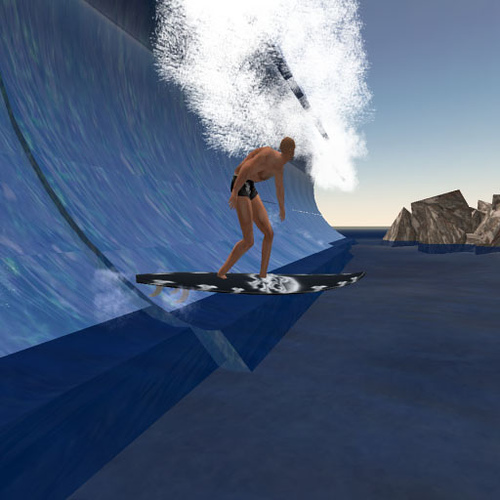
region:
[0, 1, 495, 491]
Virtual picture of a surfboarding man.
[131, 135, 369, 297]
The man is standing on his surfboard.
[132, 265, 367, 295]
The surfboard is black and white.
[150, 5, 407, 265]
The man is under a high tide.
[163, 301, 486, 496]
The water is blue.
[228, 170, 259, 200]
Man is wearing black with white stripe swimsuit.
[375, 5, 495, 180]
The sky is blue and clear.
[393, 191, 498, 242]
Background on the right is rocky.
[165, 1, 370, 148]
The wave is about to splash on the surfboarder.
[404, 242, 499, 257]
The rocks reflect on the water.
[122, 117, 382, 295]
Avatar surfing on the water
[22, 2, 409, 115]
virtual wave of water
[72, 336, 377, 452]
dark blue virtual water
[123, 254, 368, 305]
black and white surf board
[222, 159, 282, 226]
men's black swimming shorts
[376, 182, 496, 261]
virtual rocks on the water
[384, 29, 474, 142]
clear blue virtual sky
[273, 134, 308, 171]
avatar head with blonde hair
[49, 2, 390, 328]
large wave over man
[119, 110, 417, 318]
man surfing on virtual water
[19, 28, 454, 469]
This is an animation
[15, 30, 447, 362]
This is a surfer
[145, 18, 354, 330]
The man is surfing a wave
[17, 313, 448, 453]
This water is very blue and transparent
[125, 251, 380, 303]
This surfboard is black and white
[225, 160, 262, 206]
The man is wearing black shorts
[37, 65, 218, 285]
This is a wave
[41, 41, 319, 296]
The wave is bigger than the man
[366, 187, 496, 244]
These are rocks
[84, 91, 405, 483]
This takes place by the ocean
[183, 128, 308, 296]
Man in the foreground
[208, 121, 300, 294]
Man is surf boarding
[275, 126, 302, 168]
A side view of a man's head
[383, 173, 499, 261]
Large rocks in the background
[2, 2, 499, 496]
Photo is in 3D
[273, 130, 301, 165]
Man in the foreground is bald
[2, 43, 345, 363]
A water wave is behind the man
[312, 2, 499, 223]
The sky is clear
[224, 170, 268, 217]
Man is wearing swim trunks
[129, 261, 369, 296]
Surf board is black and white in color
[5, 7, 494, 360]
an avatar surfing on SecondLife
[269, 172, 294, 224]
the arm of a man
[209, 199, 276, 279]
the legs of a man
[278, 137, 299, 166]
the head of a man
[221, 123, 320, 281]
an avatar wearing a bathing suit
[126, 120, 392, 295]
an avatar on a surfboard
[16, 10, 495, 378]
a computer generated picture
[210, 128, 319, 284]
a computer generated man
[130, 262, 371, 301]
a black and white surfboard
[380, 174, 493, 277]
computer generated rocks